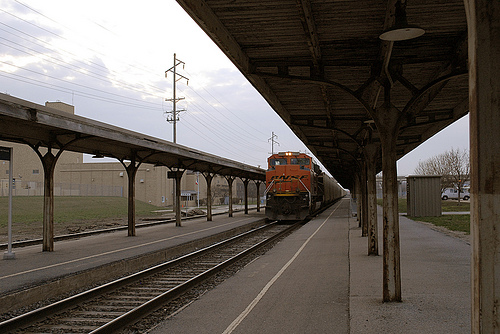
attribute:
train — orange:
[242, 138, 327, 237]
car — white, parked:
[447, 176, 472, 197]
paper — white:
[276, 158, 286, 171]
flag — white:
[1, 144, 11, 162]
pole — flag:
[0, 149, 15, 257]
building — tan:
[90, 169, 173, 202]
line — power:
[52, 47, 148, 107]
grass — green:
[97, 189, 112, 210]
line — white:
[73, 221, 152, 282]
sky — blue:
[115, 95, 160, 124]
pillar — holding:
[340, 133, 422, 295]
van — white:
[430, 182, 478, 202]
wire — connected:
[20, 24, 176, 124]